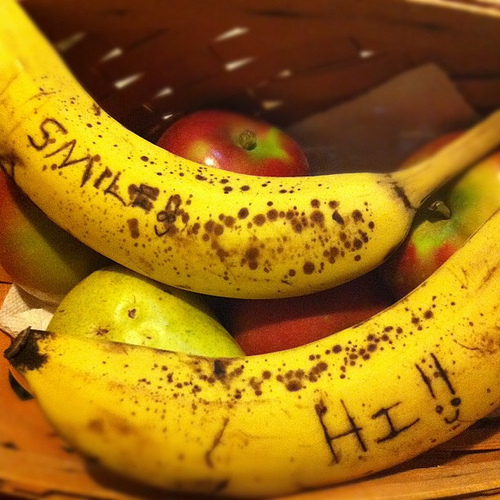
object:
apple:
[378, 131, 499, 302]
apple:
[0, 170, 109, 306]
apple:
[157, 109, 314, 181]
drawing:
[26, 117, 181, 237]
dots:
[87, 414, 121, 442]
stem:
[241, 133, 259, 149]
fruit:
[45, 264, 246, 358]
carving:
[313, 350, 465, 468]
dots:
[149, 414, 205, 462]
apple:
[223, 268, 393, 358]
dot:
[165, 171, 379, 289]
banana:
[0, 204, 499, 499]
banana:
[0, 0, 500, 301]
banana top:
[2, 326, 46, 366]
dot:
[130, 271, 441, 421]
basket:
[0, 0, 500, 500]